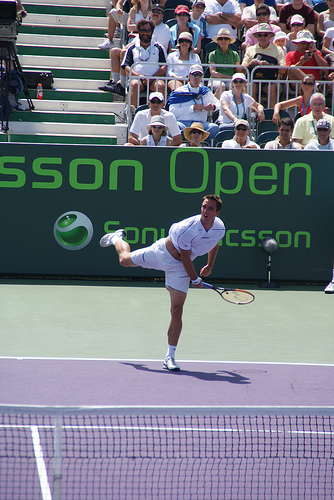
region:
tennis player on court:
[98, 193, 253, 372]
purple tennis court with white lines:
[1, 356, 332, 498]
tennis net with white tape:
[2, 401, 325, 497]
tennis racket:
[190, 277, 254, 303]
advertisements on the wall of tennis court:
[1, 150, 311, 249]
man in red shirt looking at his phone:
[284, 29, 325, 77]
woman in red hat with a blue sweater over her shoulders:
[171, 6, 202, 52]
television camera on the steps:
[1, 3, 33, 111]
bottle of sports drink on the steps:
[36, 83, 42, 99]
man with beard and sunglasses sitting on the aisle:
[119, 20, 165, 93]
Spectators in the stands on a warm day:
[93, 0, 333, 159]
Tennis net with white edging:
[4, 397, 333, 497]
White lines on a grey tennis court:
[1, 350, 324, 486]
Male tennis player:
[91, 187, 259, 378]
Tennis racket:
[183, 268, 259, 311]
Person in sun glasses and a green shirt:
[206, 27, 243, 81]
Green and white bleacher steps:
[36, 4, 126, 146]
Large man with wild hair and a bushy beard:
[120, 17, 176, 99]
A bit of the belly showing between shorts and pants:
[161, 234, 193, 265]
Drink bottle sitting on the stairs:
[33, 81, 45, 102]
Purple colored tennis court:
[59, 366, 133, 394]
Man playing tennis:
[99, 191, 260, 379]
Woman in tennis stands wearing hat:
[135, 115, 174, 150]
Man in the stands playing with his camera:
[287, 31, 326, 78]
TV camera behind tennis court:
[0, 0, 33, 135]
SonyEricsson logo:
[51, 209, 94, 253]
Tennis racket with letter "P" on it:
[192, 274, 255, 307]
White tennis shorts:
[131, 239, 191, 291]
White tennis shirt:
[165, 214, 224, 260]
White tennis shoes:
[163, 357, 178, 370]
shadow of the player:
[162, 363, 256, 392]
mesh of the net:
[192, 448, 280, 493]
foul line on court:
[22, 414, 50, 485]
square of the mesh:
[234, 468, 247, 474]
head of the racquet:
[199, 287, 263, 308]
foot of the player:
[158, 354, 184, 374]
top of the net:
[5, 401, 321, 418]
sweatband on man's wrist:
[183, 269, 207, 292]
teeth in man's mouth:
[200, 213, 209, 218]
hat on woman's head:
[141, 113, 169, 135]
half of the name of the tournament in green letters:
[2, 154, 142, 191]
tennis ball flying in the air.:
[264, 239, 279, 251]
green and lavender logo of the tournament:
[53, 209, 94, 250]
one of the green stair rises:
[12, 109, 115, 124]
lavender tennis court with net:
[4, 359, 332, 498]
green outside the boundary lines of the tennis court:
[6, 284, 330, 362]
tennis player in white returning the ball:
[100, 193, 256, 370]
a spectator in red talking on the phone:
[283, 28, 331, 80]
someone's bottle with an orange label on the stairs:
[36, 83, 43, 98]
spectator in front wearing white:
[140, 114, 171, 147]